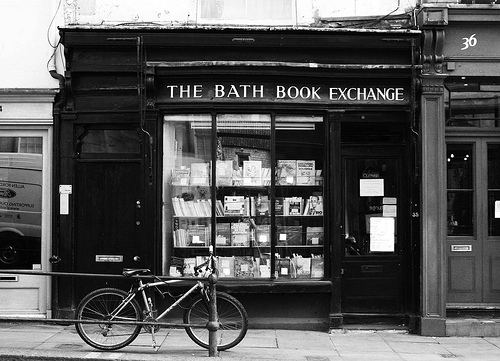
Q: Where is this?
A: This is at the store.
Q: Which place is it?
A: It is a store.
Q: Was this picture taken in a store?
A: Yes, it was taken in a store.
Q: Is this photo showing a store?
A: Yes, it is showing a store.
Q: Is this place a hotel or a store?
A: It is a store.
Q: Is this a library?
A: No, it is a store.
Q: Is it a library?
A: No, it is a store.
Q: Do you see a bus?
A: No, there are no buses.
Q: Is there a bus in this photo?
A: No, there are no buses.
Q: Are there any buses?
A: No, there are no buses.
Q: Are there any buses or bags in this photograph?
A: No, there are no buses or bags.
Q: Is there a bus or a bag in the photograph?
A: No, there are no buses or bags.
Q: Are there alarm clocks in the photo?
A: No, there are no alarm clocks.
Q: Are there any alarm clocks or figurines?
A: No, there are no alarm clocks or figurines.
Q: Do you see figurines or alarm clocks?
A: No, there are no alarm clocks or figurines.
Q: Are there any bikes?
A: Yes, there is a bike.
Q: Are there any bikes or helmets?
A: Yes, there is a bike.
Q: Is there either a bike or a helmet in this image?
A: Yes, there is a bike.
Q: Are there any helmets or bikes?
A: Yes, there is a bike.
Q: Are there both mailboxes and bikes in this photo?
A: Yes, there are both a bike and a mailbox.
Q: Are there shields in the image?
A: No, there are no shields.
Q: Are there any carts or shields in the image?
A: No, there are no shields or carts.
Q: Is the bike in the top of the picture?
A: No, the bike is in the bottom of the image.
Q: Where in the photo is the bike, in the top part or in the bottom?
A: The bike is in the bottom of the image.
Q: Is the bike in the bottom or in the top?
A: The bike is in the bottom of the image.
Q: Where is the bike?
A: The bike is on the sidewalk.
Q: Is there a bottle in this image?
A: No, there are no bottles.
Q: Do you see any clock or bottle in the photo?
A: No, there are no bottles or clocks.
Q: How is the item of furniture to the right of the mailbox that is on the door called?
A: The piece of furniture is a shelf.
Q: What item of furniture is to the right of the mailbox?
A: The piece of furniture is a shelf.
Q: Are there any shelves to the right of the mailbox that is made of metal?
A: Yes, there is a shelf to the right of the mailbox.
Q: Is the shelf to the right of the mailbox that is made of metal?
A: Yes, the shelf is to the right of the mailbox.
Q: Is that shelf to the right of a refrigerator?
A: No, the shelf is to the right of the mailbox.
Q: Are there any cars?
A: No, there are no cars.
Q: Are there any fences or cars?
A: No, there are no cars or fences.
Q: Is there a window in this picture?
A: Yes, there is a window.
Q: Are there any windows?
A: Yes, there is a window.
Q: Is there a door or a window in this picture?
A: Yes, there is a window.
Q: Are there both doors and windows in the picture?
A: Yes, there are both a window and a door.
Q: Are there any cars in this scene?
A: No, there are no cars.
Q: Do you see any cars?
A: No, there are no cars.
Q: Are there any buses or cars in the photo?
A: No, there are no cars or buses.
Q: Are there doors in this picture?
A: Yes, there is a door.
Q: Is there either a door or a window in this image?
A: Yes, there is a door.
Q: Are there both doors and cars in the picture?
A: No, there is a door but no cars.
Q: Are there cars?
A: No, there are no cars.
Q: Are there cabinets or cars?
A: No, there are no cars or cabinets.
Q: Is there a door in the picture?
A: Yes, there is a door.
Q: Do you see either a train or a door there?
A: Yes, there is a door.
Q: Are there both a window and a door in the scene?
A: Yes, there are both a door and a window.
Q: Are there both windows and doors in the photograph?
A: Yes, there are both a door and windows.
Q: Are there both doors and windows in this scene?
A: Yes, there are both a door and windows.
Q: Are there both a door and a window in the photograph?
A: Yes, there are both a door and a window.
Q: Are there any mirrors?
A: No, there are no mirrors.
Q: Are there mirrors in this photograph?
A: No, there are no mirrors.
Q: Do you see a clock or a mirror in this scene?
A: No, there are no mirrors or clocks.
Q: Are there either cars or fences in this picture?
A: No, there are no cars or fences.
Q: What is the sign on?
A: The sign is on the door.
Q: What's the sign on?
A: The sign is on the door.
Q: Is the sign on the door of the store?
A: Yes, the sign is on the door.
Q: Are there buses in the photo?
A: No, there are no buses.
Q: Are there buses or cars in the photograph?
A: No, there are no buses or cars.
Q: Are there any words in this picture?
A: Yes, there are words.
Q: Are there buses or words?
A: Yes, there are words.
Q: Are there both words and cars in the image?
A: No, there are words but no cars.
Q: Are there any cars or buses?
A: No, there are no buses or cars.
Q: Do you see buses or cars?
A: No, there are no buses or cars.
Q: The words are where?
A: The words are on the store.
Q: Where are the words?
A: The words are on the store.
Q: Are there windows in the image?
A: Yes, there is a window.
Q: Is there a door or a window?
A: Yes, there is a window.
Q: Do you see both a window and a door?
A: Yes, there are both a window and a door.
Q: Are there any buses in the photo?
A: No, there are no buses.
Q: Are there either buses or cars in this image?
A: No, there are no buses or cars.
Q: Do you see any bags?
A: No, there are no bags.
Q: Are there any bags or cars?
A: No, there are no bags or cars.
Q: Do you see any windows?
A: Yes, there are windows.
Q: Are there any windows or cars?
A: Yes, there are windows.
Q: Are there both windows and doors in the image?
A: Yes, there are both windows and a door.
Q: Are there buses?
A: No, there are no buses.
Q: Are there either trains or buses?
A: No, there are no buses or trains.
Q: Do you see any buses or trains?
A: No, there are no buses or trains.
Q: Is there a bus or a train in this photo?
A: No, there are no buses or trains.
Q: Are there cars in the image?
A: No, there are no cars.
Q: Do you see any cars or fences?
A: No, there are no cars or fences.